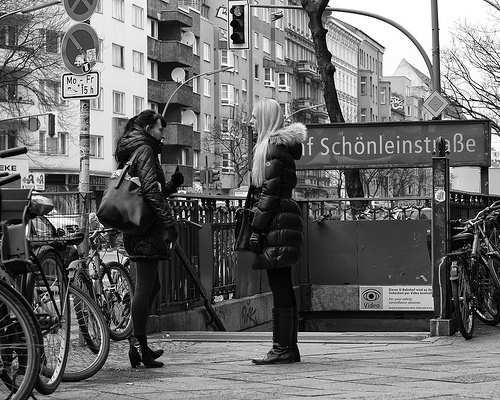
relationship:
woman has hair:
[230, 98, 311, 367] [248, 98, 283, 188]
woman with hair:
[93, 105, 184, 369] [110, 109, 168, 162]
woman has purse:
[93, 105, 184, 369] [95, 144, 163, 234]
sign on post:
[61, 71, 102, 101] [78, 100, 92, 238]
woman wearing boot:
[230, 98, 311, 367] [251, 304, 297, 366]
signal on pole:
[226, 3, 254, 53] [251, 3, 440, 127]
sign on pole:
[61, 71, 102, 101] [78, 100, 92, 238]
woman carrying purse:
[93, 105, 184, 369] [95, 144, 163, 234]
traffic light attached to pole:
[226, 3, 254, 53] [251, 3, 440, 127]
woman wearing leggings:
[93, 105, 184, 369] [126, 257, 163, 340]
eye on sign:
[359, 287, 383, 302] [356, 282, 437, 314]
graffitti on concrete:
[240, 298, 260, 326] [154, 285, 304, 334]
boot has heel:
[126, 332, 166, 372] [128, 355, 139, 371]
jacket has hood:
[248, 121, 309, 271] [265, 120, 306, 164]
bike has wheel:
[445, 204, 500, 340] [450, 259, 477, 343]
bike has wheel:
[61, 225, 138, 356] [89, 260, 137, 345]